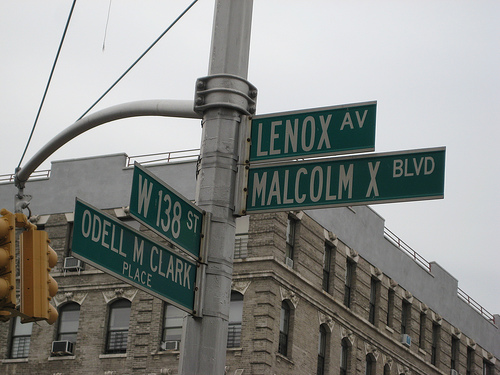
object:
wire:
[78, 0, 198, 121]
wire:
[15, 0, 77, 176]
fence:
[0, 147, 217, 186]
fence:
[379, 215, 497, 328]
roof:
[0, 144, 499, 309]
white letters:
[79, 208, 94, 239]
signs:
[242, 146, 446, 210]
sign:
[248, 97, 377, 161]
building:
[0, 146, 500, 375]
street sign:
[126, 160, 206, 261]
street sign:
[66, 193, 200, 310]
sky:
[0, 1, 498, 311]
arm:
[6, 98, 193, 186]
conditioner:
[163, 339, 178, 351]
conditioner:
[49, 340, 70, 356]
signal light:
[21, 296, 63, 323]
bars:
[111, 345, 116, 349]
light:
[21, 241, 59, 268]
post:
[176, 0, 259, 375]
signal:
[23, 226, 60, 324]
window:
[3, 304, 33, 360]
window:
[50, 299, 84, 360]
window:
[155, 293, 188, 352]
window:
[222, 290, 244, 352]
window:
[275, 294, 294, 357]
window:
[281, 212, 304, 261]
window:
[317, 238, 338, 296]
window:
[316, 320, 334, 374]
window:
[336, 334, 354, 373]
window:
[343, 253, 359, 309]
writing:
[243, 147, 445, 205]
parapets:
[250, 213, 289, 366]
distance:
[345, 53, 444, 102]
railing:
[378, 224, 435, 280]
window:
[101, 292, 134, 361]